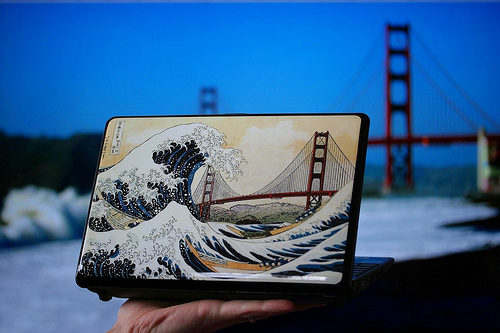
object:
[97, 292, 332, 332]
hand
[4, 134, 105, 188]
cliffside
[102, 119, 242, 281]
water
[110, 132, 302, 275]
ocean waves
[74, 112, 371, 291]
picture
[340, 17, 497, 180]
bridge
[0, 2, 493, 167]
sky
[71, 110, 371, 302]
computer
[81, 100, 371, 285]
image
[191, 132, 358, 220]
bridge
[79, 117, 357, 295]
painting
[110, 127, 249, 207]
wave